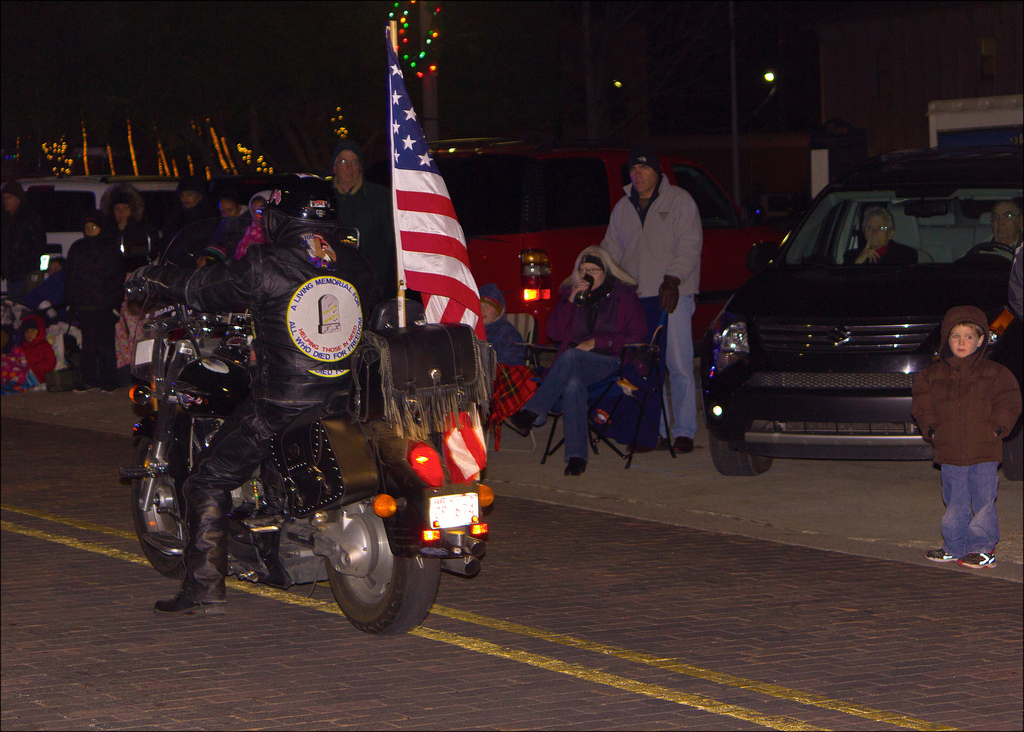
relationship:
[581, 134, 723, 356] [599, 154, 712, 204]
person has head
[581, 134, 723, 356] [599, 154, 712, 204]
person with head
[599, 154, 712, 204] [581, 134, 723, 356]
head on person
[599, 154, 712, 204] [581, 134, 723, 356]
head with person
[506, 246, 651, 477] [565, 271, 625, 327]
person in purple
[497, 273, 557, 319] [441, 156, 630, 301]
headlight on car